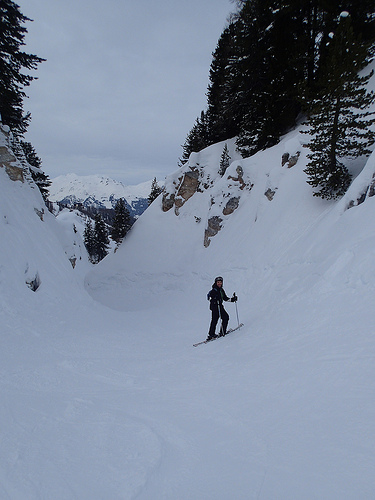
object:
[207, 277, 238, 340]
person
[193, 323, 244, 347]
skis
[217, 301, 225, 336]
ski pole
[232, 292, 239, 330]
ski pole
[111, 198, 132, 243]
evergreen tree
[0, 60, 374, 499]
snow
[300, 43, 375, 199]
evergreen tree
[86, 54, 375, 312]
hill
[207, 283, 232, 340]
clothing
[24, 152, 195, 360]
gulley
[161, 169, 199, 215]
rock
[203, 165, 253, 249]
rock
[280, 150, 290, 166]
rock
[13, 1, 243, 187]
sky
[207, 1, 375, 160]
pine trees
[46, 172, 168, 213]
mountains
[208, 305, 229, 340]
snow pants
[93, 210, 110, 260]
evergreen tree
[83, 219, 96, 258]
evergreen tree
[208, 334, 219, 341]
foot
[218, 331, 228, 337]
foot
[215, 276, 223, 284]
hat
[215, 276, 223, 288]
head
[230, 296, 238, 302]
hand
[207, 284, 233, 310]
coat